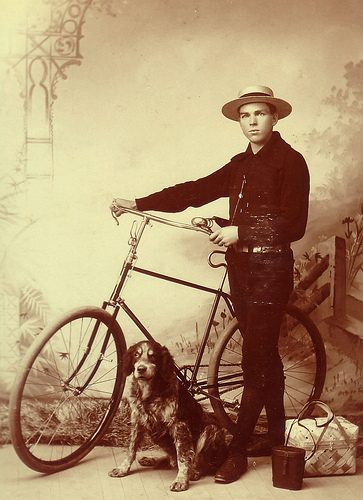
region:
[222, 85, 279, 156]
man is wearing a hat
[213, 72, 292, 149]
man is wearing a hat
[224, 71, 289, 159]
man is wearing a hat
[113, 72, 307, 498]
dog beside the man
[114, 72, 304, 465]
dog beside the man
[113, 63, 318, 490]
dog beside the man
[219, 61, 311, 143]
head of the person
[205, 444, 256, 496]
shoe on the person's foot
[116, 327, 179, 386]
head of the dog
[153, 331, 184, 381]
ear of the dog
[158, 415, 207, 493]
leg of the dog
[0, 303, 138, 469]
front tire of bike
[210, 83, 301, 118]
hat on person's head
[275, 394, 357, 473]
basket under the man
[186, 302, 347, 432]
back tire of bike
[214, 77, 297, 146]
Hat on a man's head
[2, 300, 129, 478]
A round bicycle wheel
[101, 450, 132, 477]
A paw of a dog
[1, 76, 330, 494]
Man posing with a bicycle and dog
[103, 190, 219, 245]
Handlebars of a bicycle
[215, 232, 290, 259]
Belt around a man's waist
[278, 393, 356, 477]
A bag on the ground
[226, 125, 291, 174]
Black collar of man's shirt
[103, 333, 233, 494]
A dog is sitting down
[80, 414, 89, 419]
the leaf of a tree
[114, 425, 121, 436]
the leaf of a tree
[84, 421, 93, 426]
the leaf of a tree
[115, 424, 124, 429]
the leaf of a tree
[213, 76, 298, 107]
a hat on a man's head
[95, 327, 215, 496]
a dog sitting on the ground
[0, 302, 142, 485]
the front biclyle wheel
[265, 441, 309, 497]
a small brown patch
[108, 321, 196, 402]
head of a dog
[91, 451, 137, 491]
paw of the dog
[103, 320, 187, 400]
dog looking at camera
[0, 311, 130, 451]
spokes on the tire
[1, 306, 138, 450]
bike tire next to dog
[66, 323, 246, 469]
light and dark dog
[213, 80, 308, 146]
head of the person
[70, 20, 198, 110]
wall behind the person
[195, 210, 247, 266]
hand of the person